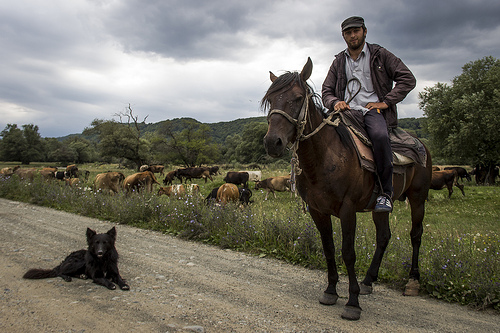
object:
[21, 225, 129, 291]
dog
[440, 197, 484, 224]
grass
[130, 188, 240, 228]
grass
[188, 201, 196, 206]
flowers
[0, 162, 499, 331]
ground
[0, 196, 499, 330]
road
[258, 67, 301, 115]
hair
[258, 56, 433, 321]
horse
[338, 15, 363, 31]
hat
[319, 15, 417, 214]
man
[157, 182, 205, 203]
cattle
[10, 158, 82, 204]
grass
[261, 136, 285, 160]
nose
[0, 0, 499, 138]
sky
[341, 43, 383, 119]
shirt